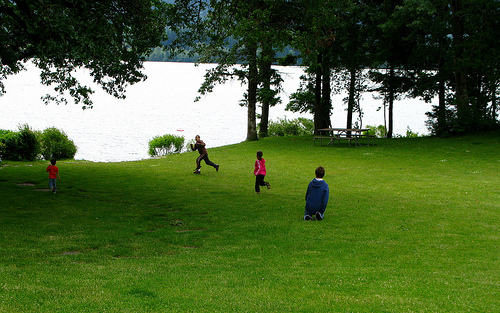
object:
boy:
[302, 165, 331, 221]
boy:
[45, 159, 61, 193]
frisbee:
[176, 127, 185, 132]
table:
[318, 127, 372, 146]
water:
[0, 57, 499, 166]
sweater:
[303, 178, 329, 215]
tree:
[163, 1, 290, 143]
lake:
[0, 57, 499, 165]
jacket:
[253, 158, 267, 176]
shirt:
[46, 164, 58, 178]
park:
[0, 0, 499, 313]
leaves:
[68, 19, 120, 49]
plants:
[145, 134, 185, 157]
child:
[252, 149, 274, 195]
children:
[187, 134, 220, 176]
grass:
[217, 272, 273, 302]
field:
[0, 133, 499, 312]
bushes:
[35, 125, 78, 162]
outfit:
[190, 140, 219, 174]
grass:
[137, 230, 174, 255]